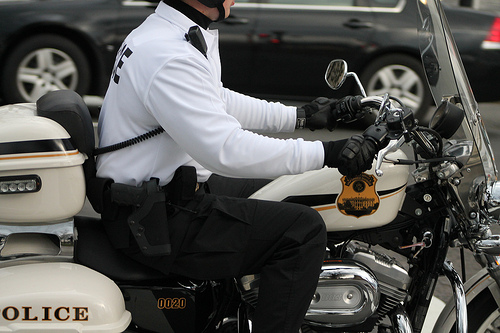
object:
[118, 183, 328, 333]
pants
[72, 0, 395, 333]
man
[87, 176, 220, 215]
belt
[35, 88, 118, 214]
seat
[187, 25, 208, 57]
radio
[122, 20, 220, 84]
shoulder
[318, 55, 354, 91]
mirror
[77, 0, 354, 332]
uniform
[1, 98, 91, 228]
storage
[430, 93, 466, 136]
speedometer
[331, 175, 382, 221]
badge emblem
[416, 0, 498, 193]
front windshield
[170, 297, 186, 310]
number 20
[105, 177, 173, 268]
gun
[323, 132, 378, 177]
glove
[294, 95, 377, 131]
glove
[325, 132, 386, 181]
handlebars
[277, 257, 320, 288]
black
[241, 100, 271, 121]
white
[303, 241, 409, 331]
engine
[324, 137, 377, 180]
hands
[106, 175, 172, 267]
gun holster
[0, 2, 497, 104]
black car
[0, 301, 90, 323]
word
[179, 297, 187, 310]
number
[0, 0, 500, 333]
motorcycle